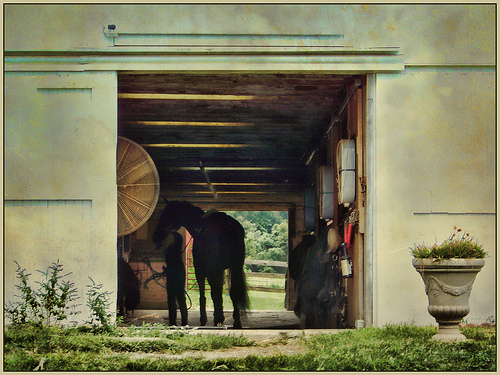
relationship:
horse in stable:
[151, 199, 254, 331] [7, 3, 498, 335]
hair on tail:
[225, 226, 251, 306] [218, 218, 255, 316]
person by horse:
[159, 222, 189, 274] [164, 199, 232, 249]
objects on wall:
[293, 225, 350, 322] [283, 80, 370, 344]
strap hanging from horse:
[176, 232, 195, 257] [148, 191, 252, 331]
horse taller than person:
[151, 199, 254, 331] [157, 224, 186, 330]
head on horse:
[151, 198, 196, 242] [153, 187, 245, 329]